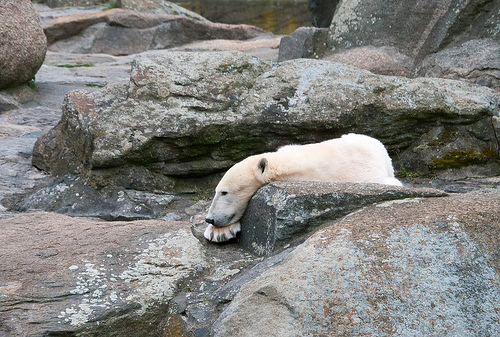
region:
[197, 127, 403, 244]
WHITE POLAR BEAR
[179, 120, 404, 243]
WHITE POLAR BEAR WITH HEAD ON PAW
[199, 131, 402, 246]
WHITE POLAR BEAR LEANING AGAINST A ROCK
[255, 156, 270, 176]
POLAR BEARS EAR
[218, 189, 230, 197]
POLAR BEARS EYE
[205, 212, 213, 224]
POLAR BEARS NOSE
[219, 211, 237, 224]
POLAR BEARS MOUTH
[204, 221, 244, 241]
POLAR BEARS PAW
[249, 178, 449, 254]
ROCK THE POLAR BEAR IS LEANING ON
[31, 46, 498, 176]
LARGE ROCK TO THE LEFT OF POLAR BEAR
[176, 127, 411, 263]
Polar bear on the rock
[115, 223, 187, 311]
Stain on the rock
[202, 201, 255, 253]
Bear has long claws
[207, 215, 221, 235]
Bear has a black nose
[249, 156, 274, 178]
Bear has a small ear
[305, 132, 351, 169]
The bears fur is white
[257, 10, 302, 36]
Yellow paint on the rock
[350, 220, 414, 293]
Brown moss on the rock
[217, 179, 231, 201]
Bear has dark colored eyes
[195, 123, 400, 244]
polar bear sitting on a large rock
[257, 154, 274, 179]
ear of a white polar bear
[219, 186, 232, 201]
eye of a white polar bear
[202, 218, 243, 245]
paw of a white polar bear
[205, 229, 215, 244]
black claw of a white polar bear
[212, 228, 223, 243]
black claw of a white polar bear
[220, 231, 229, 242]
black claw of a white polar bear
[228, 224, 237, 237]
black claw of a white polar bear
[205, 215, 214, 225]
black nose of a white polar bear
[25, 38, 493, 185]
large rock behind the polar bear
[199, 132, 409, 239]
little white bear on the river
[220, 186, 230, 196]
little right black eye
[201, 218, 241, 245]
right leg of white bear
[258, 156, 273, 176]
li8ttle furry black ear of bear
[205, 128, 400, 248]
white furry bear lying between rocks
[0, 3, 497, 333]
a bunch of rocks on a river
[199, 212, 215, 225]
little black nose of bear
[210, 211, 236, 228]
black mouth of big white bear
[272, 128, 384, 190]
white furry loin of bear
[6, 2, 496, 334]
big moldy rocks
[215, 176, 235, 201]
There are dark black eyes on this bear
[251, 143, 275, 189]
There is a large ear on this bear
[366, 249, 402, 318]
There is grey and brown on this stone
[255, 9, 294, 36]
There is some green moss that is in the distance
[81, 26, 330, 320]
Jackson Mingus is the one who took this photo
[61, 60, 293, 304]
This photo was taken in the season of summer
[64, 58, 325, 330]
This photo has a great deal of value to it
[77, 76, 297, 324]
This photo is owned by Zander Zeke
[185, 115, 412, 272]
The white animal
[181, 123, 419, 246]
A white animal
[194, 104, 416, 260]
The white polar bear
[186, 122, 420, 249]
A white polar bear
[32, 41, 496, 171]
The rock near the polar bear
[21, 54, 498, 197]
A rock near the polar bear